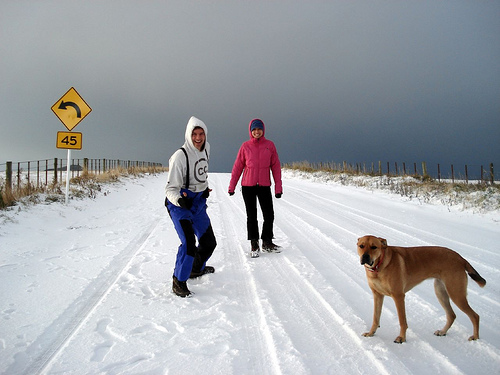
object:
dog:
[356, 235, 486, 344]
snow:
[2, 169, 499, 373]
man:
[165, 115, 217, 297]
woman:
[227, 117, 284, 258]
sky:
[0, 1, 499, 178]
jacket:
[228, 118, 283, 194]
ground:
[0, 171, 499, 375]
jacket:
[164, 115, 211, 208]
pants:
[164, 188, 217, 282]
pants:
[242, 186, 274, 240]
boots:
[251, 240, 261, 258]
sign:
[56, 131, 82, 149]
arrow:
[58, 100, 82, 118]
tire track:
[2, 208, 162, 375]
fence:
[0, 157, 162, 203]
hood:
[185, 115, 208, 151]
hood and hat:
[249, 118, 265, 140]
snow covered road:
[1, 165, 498, 374]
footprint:
[91, 341, 114, 363]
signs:
[50, 86, 92, 131]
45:
[61, 136, 77, 145]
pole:
[66, 148, 71, 197]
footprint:
[95, 319, 126, 345]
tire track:
[249, 253, 384, 375]